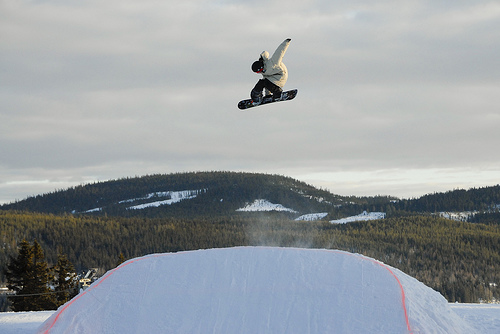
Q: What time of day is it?
A: Daytime.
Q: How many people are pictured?
A: One.